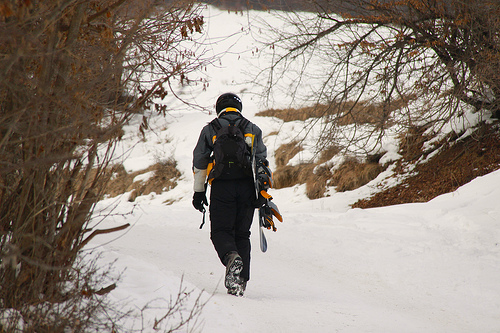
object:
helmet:
[213, 92, 244, 116]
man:
[188, 89, 284, 297]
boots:
[223, 255, 248, 289]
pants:
[206, 176, 256, 282]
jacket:
[190, 112, 275, 195]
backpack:
[208, 116, 253, 181]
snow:
[0, 0, 500, 333]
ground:
[0, 173, 500, 312]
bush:
[0, 39, 181, 281]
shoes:
[227, 273, 249, 298]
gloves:
[189, 190, 209, 216]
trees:
[371, 33, 469, 117]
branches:
[104, 6, 150, 24]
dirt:
[254, 88, 422, 130]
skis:
[196, 174, 212, 231]